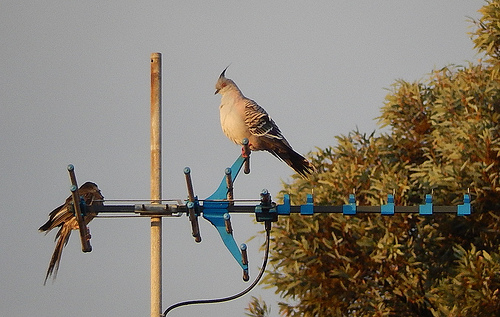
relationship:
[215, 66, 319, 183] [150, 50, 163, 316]
bird on pole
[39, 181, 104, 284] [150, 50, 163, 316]
bird on pole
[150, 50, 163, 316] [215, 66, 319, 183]
pole with bird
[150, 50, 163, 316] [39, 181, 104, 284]
pole with bird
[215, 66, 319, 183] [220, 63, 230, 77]
bird has feather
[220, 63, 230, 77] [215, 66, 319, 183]
feather on bird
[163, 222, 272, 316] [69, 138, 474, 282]
cable of antenna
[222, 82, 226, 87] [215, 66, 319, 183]
eye of bird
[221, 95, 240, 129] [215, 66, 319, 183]
chest of bird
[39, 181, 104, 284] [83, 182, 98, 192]
bird tucks head